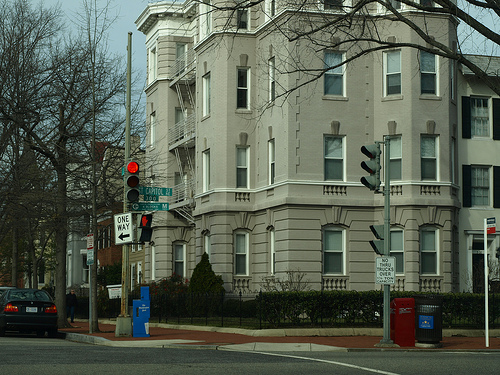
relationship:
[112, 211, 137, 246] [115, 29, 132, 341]
sign on pole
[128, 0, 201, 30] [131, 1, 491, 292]
design on wall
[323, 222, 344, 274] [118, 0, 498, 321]
window on building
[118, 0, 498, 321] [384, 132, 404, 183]
building has window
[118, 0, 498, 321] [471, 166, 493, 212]
building has window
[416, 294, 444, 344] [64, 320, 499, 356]
bin on sidewalk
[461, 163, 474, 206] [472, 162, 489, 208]
shutter on window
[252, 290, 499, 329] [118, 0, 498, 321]
hedge in front of building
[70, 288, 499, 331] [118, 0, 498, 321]
railing around building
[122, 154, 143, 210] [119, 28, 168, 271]
traffic light on pole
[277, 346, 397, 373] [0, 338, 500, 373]
line on road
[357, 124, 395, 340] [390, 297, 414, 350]
traffic signals next box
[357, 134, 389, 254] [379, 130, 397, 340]
street lights on pole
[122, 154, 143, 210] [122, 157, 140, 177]
traffic light indicates stop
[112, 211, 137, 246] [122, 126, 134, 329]
sign on post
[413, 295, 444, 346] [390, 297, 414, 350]
bin beside box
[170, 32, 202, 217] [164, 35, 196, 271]
balconies has escapes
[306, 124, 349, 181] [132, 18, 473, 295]
window on building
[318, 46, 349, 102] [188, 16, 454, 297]
window on the building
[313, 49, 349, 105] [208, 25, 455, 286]
window on the building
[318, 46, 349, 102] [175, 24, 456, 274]
window on the building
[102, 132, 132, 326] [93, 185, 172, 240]
pole with signs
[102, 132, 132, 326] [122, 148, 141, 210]
pole with light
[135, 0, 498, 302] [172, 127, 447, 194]
building with windows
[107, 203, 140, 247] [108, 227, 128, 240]
sign with arrow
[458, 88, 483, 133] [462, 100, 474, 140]
window with shutters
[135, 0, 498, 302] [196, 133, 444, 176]
building with windows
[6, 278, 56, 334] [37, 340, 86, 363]
car parked on street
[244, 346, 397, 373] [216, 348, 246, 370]
line on the road